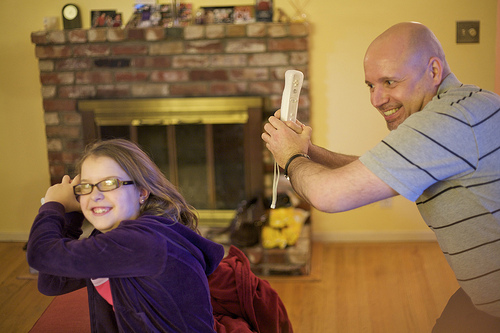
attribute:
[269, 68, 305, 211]
controller — white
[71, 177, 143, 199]
eyeglasses — brown, dark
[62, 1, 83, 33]
clock — black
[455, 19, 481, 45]
light switch — gold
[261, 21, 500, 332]
man — bald, smiling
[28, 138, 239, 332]
girl — smiling, playing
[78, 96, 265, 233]
gold trim — brass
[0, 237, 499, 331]
floor — hardwood, wood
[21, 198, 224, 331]
jacket — purple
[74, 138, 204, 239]
hair — brown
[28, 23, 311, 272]
fireplace — brick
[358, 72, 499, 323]
shirt — striped